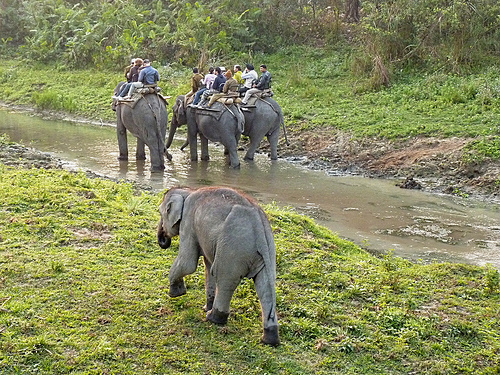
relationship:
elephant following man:
[137, 174, 291, 320] [117, 44, 154, 99]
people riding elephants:
[123, 33, 278, 107] [77, 79, 302, 180]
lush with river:
[338, 190, 421, 235] [289, 93, 442, 273]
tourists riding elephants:
[109, 58, 274, 113] [77, 79, 302, 180]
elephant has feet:
[137, 174, 291, 320] [148, 236, 215, 302]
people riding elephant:
[123, 33, 278, 107] [137, 174, 291, 320]